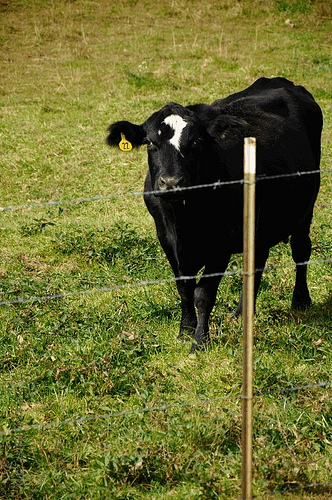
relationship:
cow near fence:
[89, 88, 330, 346] [13, 162, 138, 451]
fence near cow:
[13, 162, 138, 451] [89, 88, 330, 346]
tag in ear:
[121, 121, 138, 158] [98, 121, 124, 139]